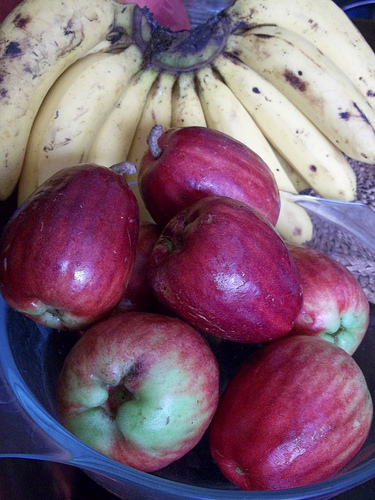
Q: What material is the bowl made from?
A: Glass.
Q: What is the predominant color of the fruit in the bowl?
A: Red.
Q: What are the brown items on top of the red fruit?
A: Stems.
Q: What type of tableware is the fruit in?
A: Bowl.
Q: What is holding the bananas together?
A: Stem.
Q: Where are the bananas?
A: Behind bowl.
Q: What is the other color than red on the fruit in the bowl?
A: Green.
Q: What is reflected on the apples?
A: Light.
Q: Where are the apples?
A: Bowl.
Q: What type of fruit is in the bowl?
A: Apples.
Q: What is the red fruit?
A: Apple.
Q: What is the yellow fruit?
A: Bananas.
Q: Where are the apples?
A: Bowl.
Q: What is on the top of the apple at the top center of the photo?
A: Stem.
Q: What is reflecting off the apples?
A: Light.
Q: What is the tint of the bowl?
A: Blue.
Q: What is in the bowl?
A: Apples.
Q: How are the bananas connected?
A: By the stem.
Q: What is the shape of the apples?
A: Oval.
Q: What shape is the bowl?
A: Circle.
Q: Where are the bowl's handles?
A: On the sides of the bowl.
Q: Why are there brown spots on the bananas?
A: The bananas are ripening.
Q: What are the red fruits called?
A: Apples.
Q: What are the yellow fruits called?
A: Bananas.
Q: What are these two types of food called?
A: Fruit.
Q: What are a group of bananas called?
A: A bunch.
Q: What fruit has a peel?
A: The bananas.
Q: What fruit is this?
A: Apples, bananas.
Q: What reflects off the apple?
A: Light.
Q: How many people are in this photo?
A: Zero.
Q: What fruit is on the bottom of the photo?
A: Apples.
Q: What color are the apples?
A: Red.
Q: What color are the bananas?
A: Yellow.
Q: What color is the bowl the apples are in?
A: Clear.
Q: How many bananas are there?
A: Nine.